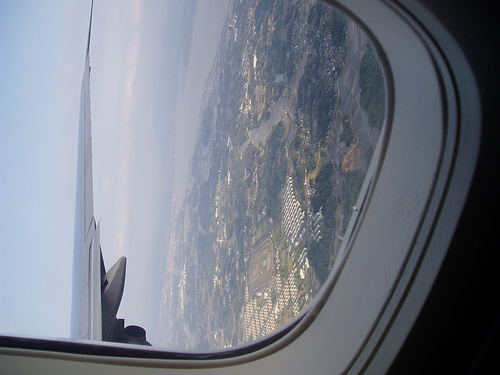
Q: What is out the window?
A: A plane wing.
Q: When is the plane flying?
A: Daytime.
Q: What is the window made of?
A: Glass.